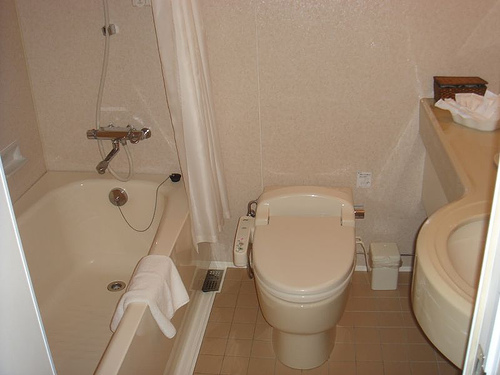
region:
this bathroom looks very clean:
[5, 1, 499, 373]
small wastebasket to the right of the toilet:
[361, 233, 406, 296]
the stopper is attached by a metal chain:
[106, 168, 186, 240]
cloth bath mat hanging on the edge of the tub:
[103, 244, 195, 347]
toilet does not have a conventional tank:
[248, 183, 362, 374]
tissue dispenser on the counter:
[430, 82, 499, 134]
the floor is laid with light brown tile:
[192, 257, 427, 374]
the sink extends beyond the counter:
[401, 183, 497, 373]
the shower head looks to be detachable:
[76, 1, 157, 183]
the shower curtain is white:
[145, 2, 242, 253]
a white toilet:
[226, 167, 370, 374]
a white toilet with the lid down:
[232, 173, 377, 365]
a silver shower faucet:
[63, 117, 160, 179]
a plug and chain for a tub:
[98, 169, 189, 240]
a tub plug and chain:
[103, 171, 193, 234]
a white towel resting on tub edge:
[91, 244, 198, 341]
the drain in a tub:
[100, 267, 133, 303]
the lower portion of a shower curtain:
[160, 108, 234, 258]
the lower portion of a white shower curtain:
[133, 5, 234, 272]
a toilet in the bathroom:
[238, 166, 370, 366]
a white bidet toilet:
[231, 183, 365, 368]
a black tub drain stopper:
[167, 172, 187, 190]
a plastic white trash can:
[363, 228, 405, 297]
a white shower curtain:
[142, 0, 227, 261]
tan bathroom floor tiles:
[188, 235, 459, 370]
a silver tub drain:
[98, 278, 133, 293]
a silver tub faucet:
[80, 115, 148, 185]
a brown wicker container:
[428, 59, 490, 111]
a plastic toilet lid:
[254, 196, 354, 303]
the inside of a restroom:
[6, 1, 486, 371]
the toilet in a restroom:
[236, 173, 369, 365]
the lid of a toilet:
[254, 225, 359, 291]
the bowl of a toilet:
[253, 288, 363, 368]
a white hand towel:
[98, 249, 188, 340]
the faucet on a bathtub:
[79, 120, 154, 176]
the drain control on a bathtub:
[103, 182, 132, 217]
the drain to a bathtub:
[102, 275, 127, 299]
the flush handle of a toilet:
[351, 199, 369, 221]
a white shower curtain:
[148, 1, 229, 259]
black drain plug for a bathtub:
[160, 166, 187, 188]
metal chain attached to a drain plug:
[108, 194, 162, 241]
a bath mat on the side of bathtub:
[93, 244, 211, 346]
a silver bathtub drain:
[95, 273, 130, 297]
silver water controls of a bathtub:
[79, 110, 156, 181]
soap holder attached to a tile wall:
[2, 136, 33, 183]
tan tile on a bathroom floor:
[226, 332, 262, 364]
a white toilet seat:
[245, 189, 365, 308]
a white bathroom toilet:
[232, 176, 370, 370]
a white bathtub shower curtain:
[147, 26, 244, 258]